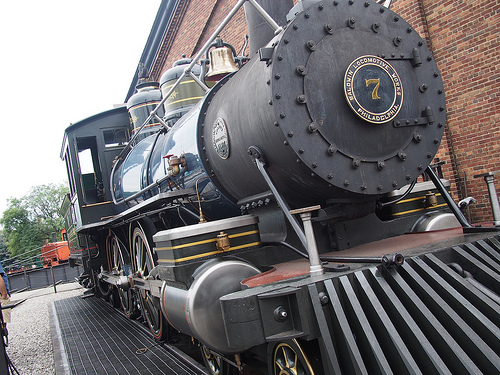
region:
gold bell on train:
[206, 46, 254, 98]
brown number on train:
[345, 59, 387, 100]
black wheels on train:
[80, 209, 177, 339]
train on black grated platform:
[53, 278, 188, 372]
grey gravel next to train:
[5, 306, 43, 373]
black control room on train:
[48, 119, 135, 301]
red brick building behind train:
[139, 6, 498, 216]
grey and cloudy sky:
[24, 51, 88, 118]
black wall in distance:
[7, 265, 79, 287]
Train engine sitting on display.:
[57, 1, 499, 374]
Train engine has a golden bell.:
[204, 44, 239, 78]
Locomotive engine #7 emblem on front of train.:
[341, 54, 403, 126]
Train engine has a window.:
[98, 122, 133, 149]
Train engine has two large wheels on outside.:
[102, 218, 172, 343]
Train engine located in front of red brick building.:
[122, 0, 498, 226]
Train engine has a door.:
[72, 134, 109, 208]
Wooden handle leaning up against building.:
[461, 169, 473, 224]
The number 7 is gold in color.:
[362, 76, 383, 101]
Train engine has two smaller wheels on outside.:
[192, 336, 322, 373]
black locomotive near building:
[45, 21, 407, 351]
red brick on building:
[428, 21, 498, 116]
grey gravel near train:
[0, 305, 45, 369]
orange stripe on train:
[142, 231, 274, 269]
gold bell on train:
[192, 46, 270, 99]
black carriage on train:
[69, 98, 136, 233]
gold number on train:
[328, 55, 417, 150]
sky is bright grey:
[7, 15, 109, 86]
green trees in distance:
[5, 185, 65, 252]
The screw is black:
[303, 116, 321, 137]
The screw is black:
[321, 137, 340, 158]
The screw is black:
[348, 148, 363, 170]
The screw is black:
[372, 153, 389, 174]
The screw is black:
[392, 145, 410, 167]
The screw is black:
[408, 128, 425, 148]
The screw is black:
[413, 80, 432, 96]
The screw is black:
[288, 87, 310, 109]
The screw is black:
[292, 59, 307, 82]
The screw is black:
[296, 31, 324, 63]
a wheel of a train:
[129, 233, 162, 323]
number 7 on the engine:
[361, 75, 392, 104]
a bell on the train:
[210, 44, 232, 74]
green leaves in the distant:
[13, 235, 40, 253]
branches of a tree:
[36, 188, 65, 231]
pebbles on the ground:
[18, 314, 41, 373]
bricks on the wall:
[448, 15, 496, 87]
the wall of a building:
[446, 5, 499, 154]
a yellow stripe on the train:
[174, 238, 216, 251]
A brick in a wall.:
[454, 72, 461, 79]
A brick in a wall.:
[452, 29, 464, 36]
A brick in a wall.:
[463, 97, 473, 104]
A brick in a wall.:
[459, 123, 467, 128]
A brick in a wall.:
[458, 135, 475, 140]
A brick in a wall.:
[465, 150, 472, 160]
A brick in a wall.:
[474, 122, 487, 127]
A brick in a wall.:
[480, 95, 487, 100]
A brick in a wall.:
[473, 72, 480, 77]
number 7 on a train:
[345, 48, 407, 132]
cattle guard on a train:
[281, 241, 496, 373]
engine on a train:
[106, 93, 287, 237]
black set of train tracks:
[50, 283, 233, 374]